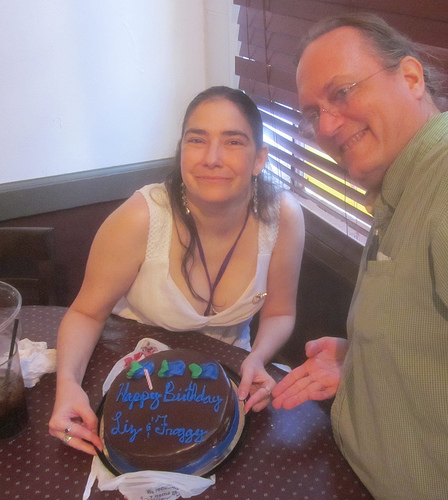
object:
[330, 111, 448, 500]
shirt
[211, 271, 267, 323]
boob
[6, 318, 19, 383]
stirrer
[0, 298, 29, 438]
drink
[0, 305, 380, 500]
tablecloth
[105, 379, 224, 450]
frosting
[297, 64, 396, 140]
glasses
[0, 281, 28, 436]
clear glass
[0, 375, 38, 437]
soda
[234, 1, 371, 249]
brown shutters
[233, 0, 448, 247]
window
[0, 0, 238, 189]
wall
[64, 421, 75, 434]
rings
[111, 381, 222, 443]
writing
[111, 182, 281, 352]
shirt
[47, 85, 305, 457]
lady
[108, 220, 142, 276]
light skinned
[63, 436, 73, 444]
ring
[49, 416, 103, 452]
finger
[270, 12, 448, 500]
man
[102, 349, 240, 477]
birthday cake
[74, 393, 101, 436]
woman's finger